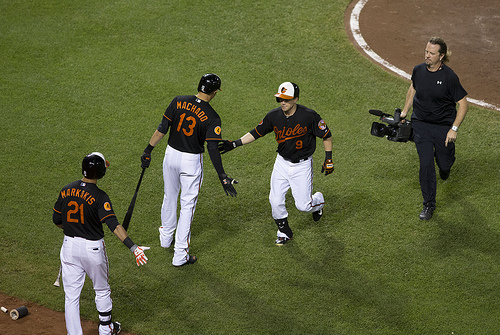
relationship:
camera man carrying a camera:
[399, 38, 469, 219] [368, 108, 413, 142]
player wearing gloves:
[217, 81, 334, 247] [315, 157, 340, 181]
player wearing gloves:
[39, 194, 147, 314] [219, 138, 357, 180]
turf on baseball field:
[78, 51, 163, 97] [1, 1, 498, 333]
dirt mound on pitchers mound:
[364, 49, 403, 124] [384, 13, 494, 68]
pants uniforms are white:
[154, 143, 230, 277] [83, 258, 128, 335]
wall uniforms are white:
[265, 81, 412, 131] [83, 258, 128, 335]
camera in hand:
[368, 104, 413, 142] [368, 109, 407, 140]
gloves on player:
[204, 135, 241, 197] [217, 81, 334, 247]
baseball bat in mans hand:
[120, 169, 145, 231] [144, 144, 152, 186]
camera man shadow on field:
[396, 35, 468, 221] [1, 1, 498, 333]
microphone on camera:
[368, 107, 390, 117] [368, 104, 413, 142]